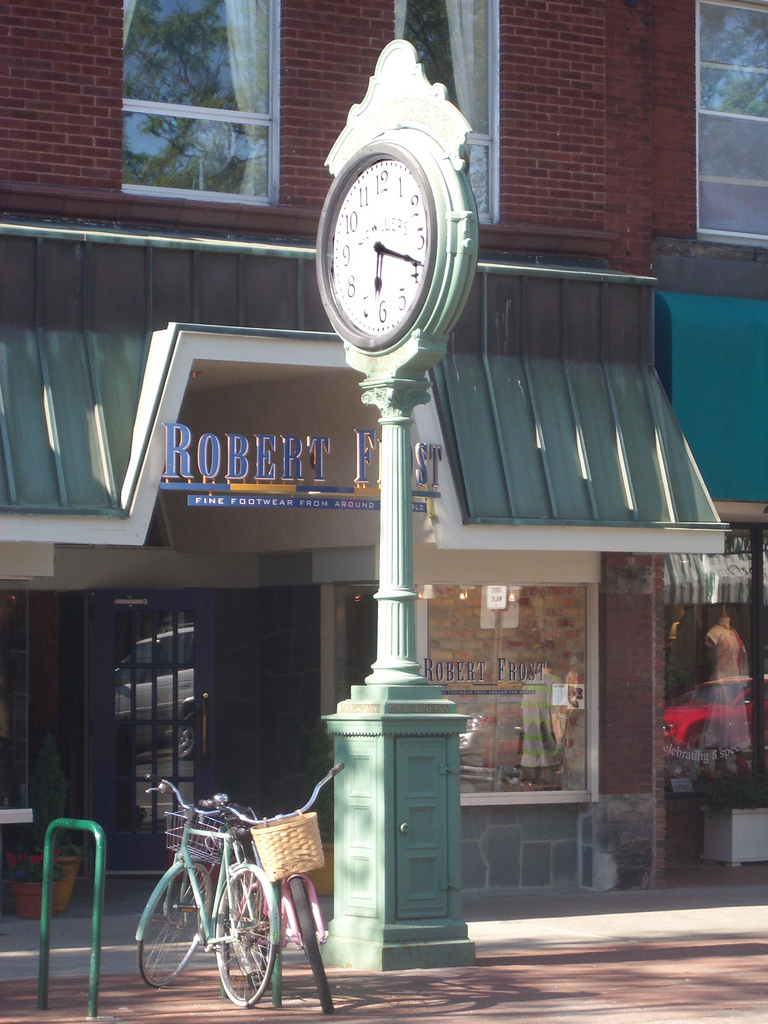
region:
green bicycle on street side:
[108, 829, 267, 1021]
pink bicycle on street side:
[226, 779, 357, 1008]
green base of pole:
[319, 669, 469, 970]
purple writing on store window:
[422, 652, 556, 691]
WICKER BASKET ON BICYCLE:
[255, 810, 332, 865]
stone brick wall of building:
[473, 819, 577, 901]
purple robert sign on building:
[133, 417, 441, 522]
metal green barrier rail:
[20, 810, 105, 1018]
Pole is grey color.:
[332, 351, 477, 967]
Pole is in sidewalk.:
[340, 394, 472, 985]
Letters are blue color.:
[171, 409, 450, 529]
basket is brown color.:
[247, 808, 334, 888]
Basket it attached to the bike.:
[215, 788, 348, 1005]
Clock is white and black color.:
[316, 128, 442, 369]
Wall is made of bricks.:
[27, 26, 678, 246]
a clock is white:
[308, 131, 458, 366]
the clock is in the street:
[301, 28, 490, 984]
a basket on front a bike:
[199, 752, 353, 902]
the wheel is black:
[282, 870, 347, 1020]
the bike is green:
[124, 772, 288, 1013]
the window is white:
[111, 1, 295, 221]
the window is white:
[685, 1, 765, 252]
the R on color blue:
[154, 415, 195, 488]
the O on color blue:
[192, 423, 229, 484]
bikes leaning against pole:
[133, 761, 360, 1013]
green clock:
[314, 37, 476, 978]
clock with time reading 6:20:
[312, 138, 443, 356]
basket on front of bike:
[244, 806, 331, 886]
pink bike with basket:
[199, 761, 348, 1012]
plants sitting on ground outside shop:
[6, 735, 86, 925]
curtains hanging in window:
[114, 1, 290, 214]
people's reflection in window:
[504, 653, 591, 797]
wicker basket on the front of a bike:
[250, 810, 326, 879]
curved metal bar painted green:
[33, 812, 108, 1016]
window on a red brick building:
[396, 3, 496, 221]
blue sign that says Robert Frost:
[164, 413, 440, 510]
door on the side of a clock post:
[392, 734, 450, 922]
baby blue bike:
[132, 776, 281, 1004]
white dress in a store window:
[702, 607, 752, 751]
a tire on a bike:
[224, 845, 265, 942]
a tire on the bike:
[150, 880, 232, 986]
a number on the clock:
[357, 302, 385, 326]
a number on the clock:
[375, 279, 413, 315]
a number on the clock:
[350, 285, 375, 322]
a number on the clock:
[342, 273, 358, 301]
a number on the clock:
[333, 244, 360, 268]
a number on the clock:
[322, 191, 374, 229]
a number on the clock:
[353, 159, 374, 207]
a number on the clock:
[401, 180, 428, 207]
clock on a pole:
[291, 38, 492, 983]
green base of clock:
[298, 672, 482, 987]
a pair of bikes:
[123, 745, 369, 1018]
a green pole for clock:
[342, 381, 434, 661]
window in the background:
[417, 576, 592, 797]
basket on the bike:
[241, 802, 333, 885]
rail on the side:
[23, 790, 121, 1008]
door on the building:
[70, 576, 202, 823]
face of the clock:
[280, 136, 451, 345]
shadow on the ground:
[32, 931, 767, 1020]